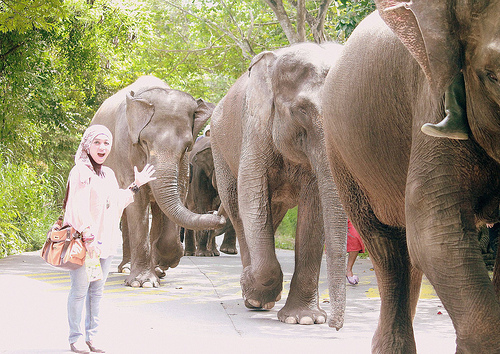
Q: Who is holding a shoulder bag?
A: The woman is holding the shoulder bag.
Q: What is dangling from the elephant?
A: A rider's foot.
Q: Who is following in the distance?
A: A small elephant.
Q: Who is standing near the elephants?
A: A woman is standing near the elephants.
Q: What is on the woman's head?
A: A head wrap.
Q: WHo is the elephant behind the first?
A: The second elephant.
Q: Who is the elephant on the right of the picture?
A: The first elephant.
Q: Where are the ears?
A: On elephant.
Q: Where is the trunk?
A: On elephant.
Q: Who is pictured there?
A: A Woman.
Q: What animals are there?
A: Elephants.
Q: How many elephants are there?
A: Four.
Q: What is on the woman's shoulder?
A: A purse.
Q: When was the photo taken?
A: Daytime.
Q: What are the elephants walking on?
A: A road.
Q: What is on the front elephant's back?
A: A person.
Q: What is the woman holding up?
A: Her hand.